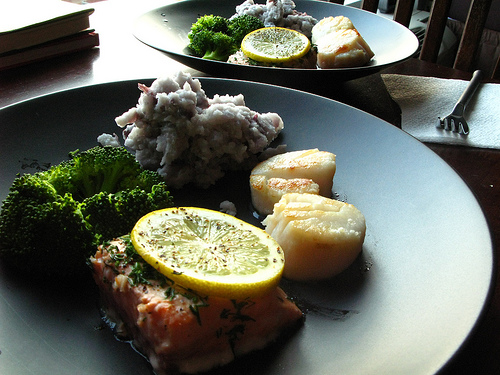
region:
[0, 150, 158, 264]
Cooked green broccoli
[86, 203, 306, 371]
Cooked salmon with lemon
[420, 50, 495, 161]
silver fork on white napkin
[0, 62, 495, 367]
Perfectly cooked seafood dish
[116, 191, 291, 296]
Sliced lemon with parsley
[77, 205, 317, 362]
Lemon herb cooked salmon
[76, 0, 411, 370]
two perfectly plated dishes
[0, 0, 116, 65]
stack of books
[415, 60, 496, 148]
fork on white napkin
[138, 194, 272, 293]
a lemon slice on top of a fish fillet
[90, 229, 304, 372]
a pink fillet of fish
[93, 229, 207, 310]
green herbs on a fish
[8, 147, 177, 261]
broccoli on a plate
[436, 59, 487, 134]
a fork on a napkin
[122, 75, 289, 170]
a white mixed salad on a plate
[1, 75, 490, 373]
a large white plate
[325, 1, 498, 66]
a wood chair back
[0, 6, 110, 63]
two books on a table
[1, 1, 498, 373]
a wooden table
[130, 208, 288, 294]
Lemon on top of fish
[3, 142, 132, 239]
Green brocclli on plate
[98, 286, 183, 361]
Piece of salmon under lemon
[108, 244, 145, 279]
Oregano on top of salmon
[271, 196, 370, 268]
Shell fish on plate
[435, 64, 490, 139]
Silver fork on napkin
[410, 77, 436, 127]
White napkin under fork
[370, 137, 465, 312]
Blue plate on table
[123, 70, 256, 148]
Mashed potato next to brocclli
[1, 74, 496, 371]
Plate of food on table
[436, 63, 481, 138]
silver fork on a napkin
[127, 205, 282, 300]
lemon slice with seasoning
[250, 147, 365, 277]
two fried scallops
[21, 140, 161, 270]
broccoli florets on a plate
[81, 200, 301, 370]
salmon with lemon slice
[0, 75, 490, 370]
seafood meal on a blue plate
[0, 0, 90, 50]
book with dust jacket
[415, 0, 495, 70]
brown wooden chair with back slats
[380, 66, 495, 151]
blue cloth napkin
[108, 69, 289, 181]
crab rice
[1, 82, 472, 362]
a white plate with seafood and rice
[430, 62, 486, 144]
a fork on a white cloth napkin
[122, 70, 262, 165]
white rice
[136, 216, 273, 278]
a slice of lemon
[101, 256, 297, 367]
sushi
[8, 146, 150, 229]
steamed broccoli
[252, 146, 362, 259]
two scallops on a white plate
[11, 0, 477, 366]
two plates with broccoli, sea food and rice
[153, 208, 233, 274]
pepper on a lemon slice